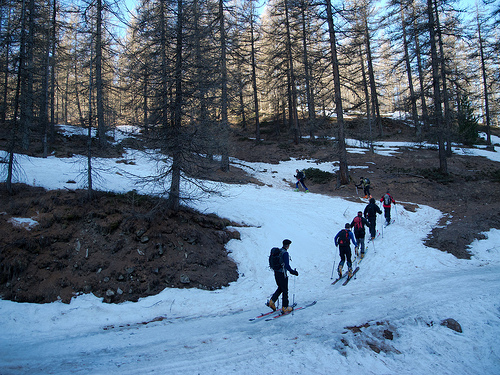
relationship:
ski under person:
[248, 300, 318, 322] [265, 238, 299, 314]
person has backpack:
[265, 238, 299, 314] [268, 247, 284, 272]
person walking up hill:
[265, 238, 299, 314] [0, 118, 499, 375]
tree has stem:
[133, 0, 226, 206] [170, 1, 184, 208]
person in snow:
[293, 169, 310, 193] [0, 124, 499, 374]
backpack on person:
[268, 247, 284, 272] [265, 238, 299, 314]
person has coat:
[265, 238, 299, 314] [275, 247, 292, 276]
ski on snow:
[248, 300, 318, 322] [0, 124, 499, 374]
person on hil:
[293, 169, 310, 193] [0, 118, 499, 375]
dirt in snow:
[1, 180, 262, 302] [0, 124, 499, 374]